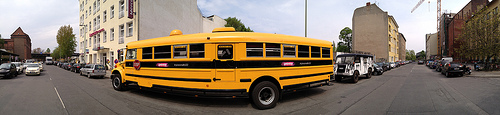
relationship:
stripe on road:
[55, 75, 74, 111] [361, 78, 445, 95]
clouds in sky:
[22, 6, 62, 25] [250, 5, 283, 19]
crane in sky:
[411, 0, 448, 30] [250, 5, 283, 19]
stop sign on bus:
[127, 58, 142, 69] [117, 17, 336, 110]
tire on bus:
[236, 76, 286, 110] [117, 17, 336, 110]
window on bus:
[211, 47, 238, 62] [117, 17, 336, 110]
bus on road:
[265, 17, 350, 89] [361, 78, 445, 95]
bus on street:
[265, 17, 350, 89] [112, 98, 134, 106]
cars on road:
[1, 55, 100, 79] [361, 78, 445, 95]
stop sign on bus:
[127, 58, 142, 69] [265, 17, 350, 89]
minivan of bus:
[76, 64, 106, 79] [265, 17, 350, 89]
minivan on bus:
[76, 64, 106, 79] [265, 17, 350, 89]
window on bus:
[211, 47, 238, 62] [265, 17, 350, 89]